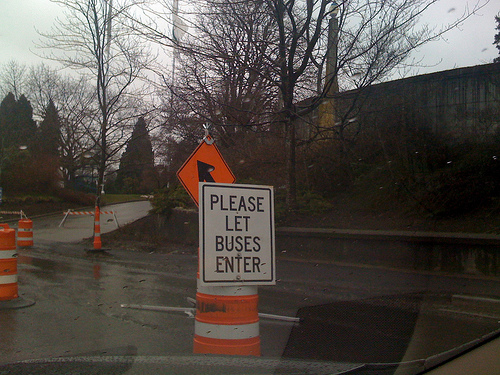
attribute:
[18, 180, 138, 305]
cones — traffic, orange, white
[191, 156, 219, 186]
arrow — Black 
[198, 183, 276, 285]
sign — please let buses enter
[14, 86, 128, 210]
pine trees — in background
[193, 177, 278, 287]
sign — please let buses enter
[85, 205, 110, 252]
cone — Orange , white 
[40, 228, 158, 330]
street — undergoing construction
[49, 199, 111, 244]
cement — wall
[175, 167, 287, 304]
sign — Black , white 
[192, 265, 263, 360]
traffic barrel — Orange 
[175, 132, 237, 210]
sign — requesting traffic merge, orange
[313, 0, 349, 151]
post — lamp